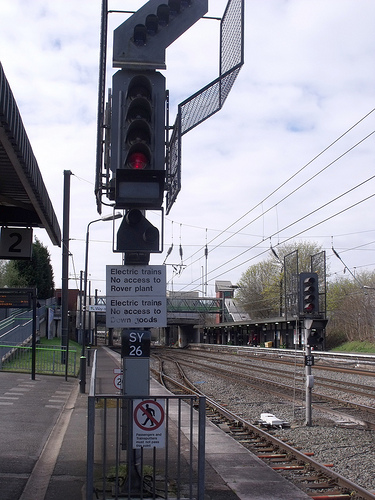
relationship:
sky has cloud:
[0, 0, 374, 302] [29, 80, 89, 115]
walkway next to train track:
[39, 328, 311, 499] [153, 338, 374, 499]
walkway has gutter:
[39, 328, 311, 499] [17, 374, 82, 498]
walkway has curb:
[39, 328, 311, 499] [105, 347, 315, 499]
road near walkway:
[0, 294, 45, 363] [39, 328, 311, 499]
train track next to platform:
[153, 338, 374, 499] [188, 314, 326, 353]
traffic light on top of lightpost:
[97, 0, 210, 213] [122, 209, 145, 477]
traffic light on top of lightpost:
[298, 270, 320, 322] [305, 346, 313, 429]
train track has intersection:
[153, 338, 374, 499] [154, 347, 186, 371]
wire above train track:
[165, 101, 374, 276] [153, 338, 374, 499]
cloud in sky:
[239, 83, 317, 126] [0, 0, 374, 302]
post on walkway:
[78, 354, 86, 393] [39, 328, 311, 499]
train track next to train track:
[153, 338, 374, 499] [149, 352, 375, 498]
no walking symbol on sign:
[135, 401, 164, 431] [133, 400, 167, 449]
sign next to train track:
[133, 400, 167, 449] [153, 338, 374, 499]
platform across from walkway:
[188, 314, 326, 353] [39, 328, 311, 499]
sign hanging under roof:
[0, 231, 34, 259] [0, 60, 61, 250]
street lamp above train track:
[81, 211, 122, 376] [153, 338, 374, 499]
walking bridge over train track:
[92, 294, 231, 327] [153, 338, 374, 499]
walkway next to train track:
[39, 328, 311, 499] [149, 352, 375, 498]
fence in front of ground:
[0, 342, 80, 375] [6, 339, 88, 378]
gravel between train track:
[349, 460, 371, 479] [153, 338, 374, 499]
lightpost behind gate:
[122, 209, 145, 477] [89, 394, 206, 499]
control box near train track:
[261, 413, 293, 430] [153, 338, 374, 499]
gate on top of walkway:
[89, 394, 206, 499] [39, 328, 311, 499]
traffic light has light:
[298, 270, 320, 322] [308, 278, 316, 286]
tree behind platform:
[323, 276, 355, 312] [188, 314, 326, 353]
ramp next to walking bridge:
[224, 294, 257, 319] [92, 294, 231, 327]